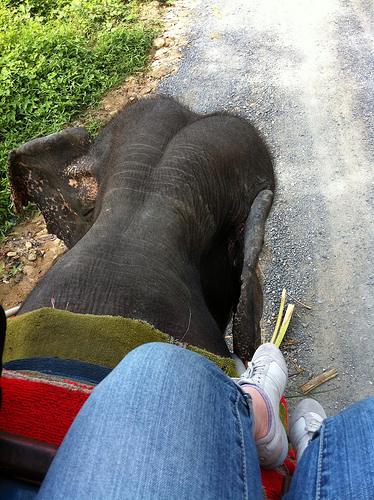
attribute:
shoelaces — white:
[244, 364, 265, 379]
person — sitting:
[34, 343, 373, 499]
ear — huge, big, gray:
[7, 126, 96, 251]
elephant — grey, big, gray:
[8, 96, 276, 363]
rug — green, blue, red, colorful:
[0, 307, 295, 500]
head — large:
[95, 96, 276, 331]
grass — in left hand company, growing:
[0, 0, 168, 239]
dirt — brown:
[2, 0, 187, 317]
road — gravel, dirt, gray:
[151, 1, 373, 424]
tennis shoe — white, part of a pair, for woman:
[236, 342, 288, 470]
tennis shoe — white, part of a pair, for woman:
[289, 398, 329, 463]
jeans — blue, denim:
[35, 343, 373, 499]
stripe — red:
[0, 371, 94, 448]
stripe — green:
[2, 307, 241, 378]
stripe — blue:
[1, 358, 112, 385]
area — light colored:
[63, 154, 97, 204]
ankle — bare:
[241, 385, 270, 442]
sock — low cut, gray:
[241, 383, 273, 433]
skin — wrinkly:
[7, 95, 277, 369]